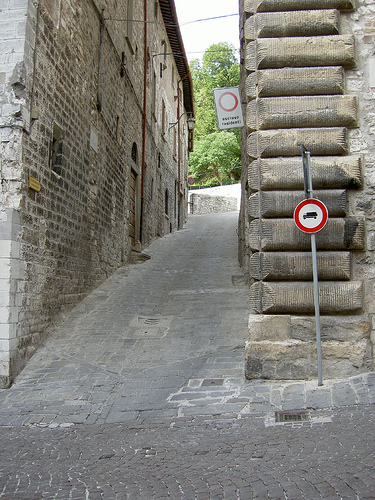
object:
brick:
[256, 94, 359, 132]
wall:
[243, 1, 374, 385]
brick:
[249, 156, 366, 192]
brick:
[241, 7, 342, 39]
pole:
[302, 151, 323, 387]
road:
[4, 208, 248, 415]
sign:
[292, 197, 329, 235]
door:
[128, 165, 141, 250]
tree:
[191, 129, 244, 185]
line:
[175, 13, 243, 28]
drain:
[274, 407, 310, 424]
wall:
[8, 5, 190, 397]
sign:
[213, 86, 244, 128]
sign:
[29, 169, 42, 192]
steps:
[124, 249, 151, 261]